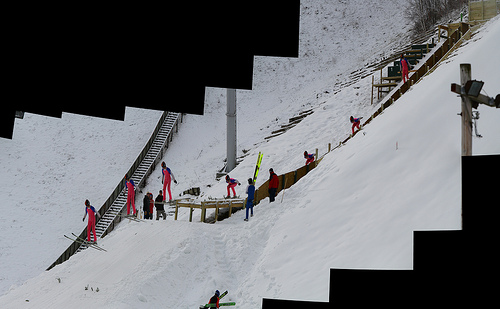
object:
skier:
[207, 289, 219, 309]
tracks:
[47, 111, 181, 271]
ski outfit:
[399, 57, 412, 83]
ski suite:
[225, 177, 239, 196]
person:
[224, 174, 241, 199]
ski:
[225, 284, 257, 291]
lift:
[171, 195, 251, 229]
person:
[123, 174, 143, 217]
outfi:
[386, 36, 439, 82]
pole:
[252, 151, 260, 184]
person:
[82, 198, 102, 244]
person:
[160, 161, 177, 204]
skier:
[349, 116, 363, 134]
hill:
[0, 0, 499, 307]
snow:
[0, 0, 499, 306]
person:
[267, 167, 280, 205]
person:
[242, 178, 256, 222]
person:
[303, 150, 317, 175]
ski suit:
[304, 153, 317, 173]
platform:
[171, 107, 425, 224]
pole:
[457, 62, 473, 157]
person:
[399, 53, 413, 85]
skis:
[237, 255, 248, 266]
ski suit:
[83, 206, 101, 243]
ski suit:
[268, 171, 280, 190]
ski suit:
[245, 183, 256, 219]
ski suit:
[161, 167, 176, 201]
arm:
[212, 296, 216, 307]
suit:
[123, 179, 140, 215]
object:
[463, 78, 486, 98]